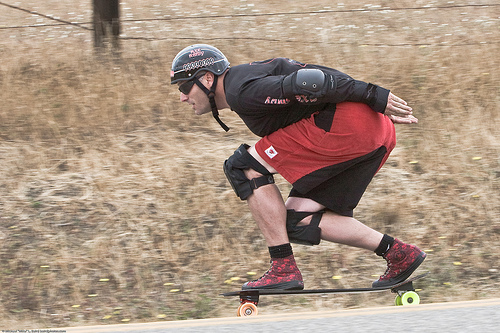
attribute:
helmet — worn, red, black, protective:
[165, 41, 274, 95]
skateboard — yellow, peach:
[227, 288, 282, 319]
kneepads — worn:
[212, 140, 291, 193]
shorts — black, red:
[248, 124, 428, 217]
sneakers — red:
[245, 249, 412, 282]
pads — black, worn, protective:
[283, 70, 322, 101]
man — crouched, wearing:
[174, 85, 430, 203]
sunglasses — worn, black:
[149, 71, 226, 105]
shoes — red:
[245, 237, 310, 290]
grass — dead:
[30, 50, 154, 151]